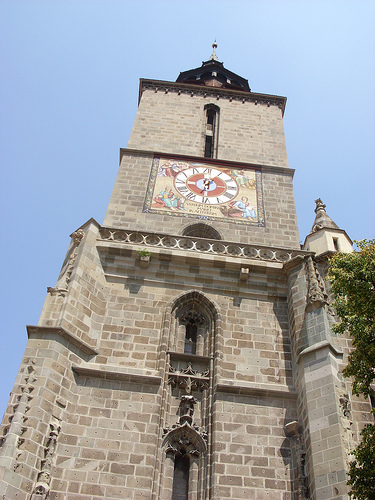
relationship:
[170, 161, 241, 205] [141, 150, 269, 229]
church clock with mural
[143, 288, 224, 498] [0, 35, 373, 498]
designs on church tower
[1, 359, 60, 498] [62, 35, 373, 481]
etching on tower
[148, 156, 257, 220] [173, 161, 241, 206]
figures painted around clock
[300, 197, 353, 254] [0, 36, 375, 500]
cupola atop side clock tower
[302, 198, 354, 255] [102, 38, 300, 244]
tower near clock tower.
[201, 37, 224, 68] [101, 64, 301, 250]
lightning rod on tower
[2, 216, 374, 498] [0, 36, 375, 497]
bottom half of clock tower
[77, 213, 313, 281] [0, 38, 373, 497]
ledge on tower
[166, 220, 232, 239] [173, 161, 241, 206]
arch below clock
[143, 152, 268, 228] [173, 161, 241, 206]
decorative square around clock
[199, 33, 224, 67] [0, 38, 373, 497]
spire on top of tower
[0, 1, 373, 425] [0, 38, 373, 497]
sky seen past tower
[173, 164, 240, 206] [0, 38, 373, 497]
church clock on side of tower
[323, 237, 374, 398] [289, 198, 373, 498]
tree in front of tower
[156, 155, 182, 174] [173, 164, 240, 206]
people around church clock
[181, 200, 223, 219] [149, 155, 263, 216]
writing underneath clock